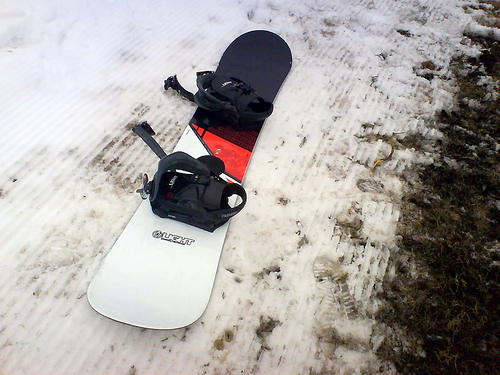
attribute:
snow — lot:
[28, 30, 101, 148]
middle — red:
[188, 112, 259, 183]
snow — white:
[2, 0, 497, 375]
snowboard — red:
[79, 28, 311, 346]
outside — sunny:
[3, 4, 499, 372]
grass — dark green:
[360, 89, 492, 374]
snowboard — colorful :
[63, 22, 333, 337]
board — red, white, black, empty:
[87, 30, 292, 330]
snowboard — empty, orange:
[70, 27, 296, 332]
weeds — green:
[411, 153, 495, 333]